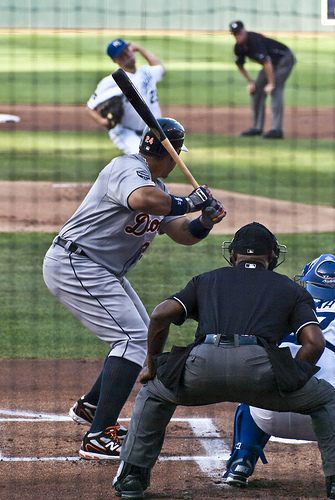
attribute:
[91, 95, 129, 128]
mitt — catcher's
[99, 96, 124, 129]
glove — baseball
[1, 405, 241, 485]
lines — white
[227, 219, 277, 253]
hat — black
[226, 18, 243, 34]
hat — black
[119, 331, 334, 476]
pants — grey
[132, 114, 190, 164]
helmet — black, baseball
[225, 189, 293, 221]
mound — pitcher's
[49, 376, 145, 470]
nike shoes — athletic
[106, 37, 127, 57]
hat — blue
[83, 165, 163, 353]
uniform — gray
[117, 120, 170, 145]
belt — black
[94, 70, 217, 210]
bat — wooden, baseball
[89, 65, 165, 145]
uniform — white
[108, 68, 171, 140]
end — black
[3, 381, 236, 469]
box — batter's